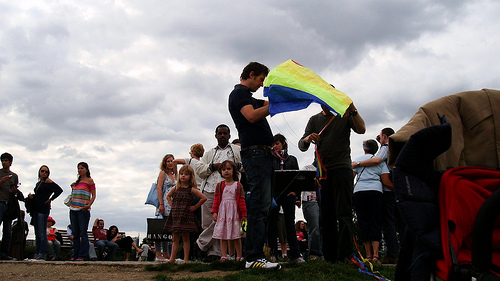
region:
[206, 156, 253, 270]
young girl in pink dress with red sweater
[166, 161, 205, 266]
young blond girl in brown dress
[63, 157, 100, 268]
woman wearing jeans and multi-colored striped shirt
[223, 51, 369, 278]
two men with yellow and blue kite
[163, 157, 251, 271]
two young girls in dresses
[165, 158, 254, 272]
one blond girl and one brunette girl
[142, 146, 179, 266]
woman in white and blue dress carrying blue bag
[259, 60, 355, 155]
yellow and blue parafoil kite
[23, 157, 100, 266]
two women wearing jeans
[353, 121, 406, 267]
man and woman wearing light blue shirts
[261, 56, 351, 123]
folded blue light green and yellow flag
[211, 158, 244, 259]
little blode girl wearing pink dress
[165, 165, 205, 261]
little blonde girl in black and red dress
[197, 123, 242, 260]
man wearing black clothes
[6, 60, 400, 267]
a bunch of people in a field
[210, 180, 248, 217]
black sweater of little blonde girl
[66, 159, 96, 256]
woman wearing multicolored t-shirt and black pants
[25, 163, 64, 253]
woman wearing black t-shirt and black pants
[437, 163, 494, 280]
red scarf lying on a bench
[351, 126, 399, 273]
woman wearing light blue t-shirt and black pants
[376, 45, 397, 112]
There is a very large cloud in the sky here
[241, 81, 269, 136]
This man is wearing a black shirt here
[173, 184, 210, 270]
This little girl is wearing a dress here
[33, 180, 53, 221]
This woman is wearing a black shirt here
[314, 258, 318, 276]
There is a green patch of grass here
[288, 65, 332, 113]
There is a rather brightly color kite here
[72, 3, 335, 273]
Jans Zander took this photo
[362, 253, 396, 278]
This woman is wearing shoes here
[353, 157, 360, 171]
This man has a watch on his left wrist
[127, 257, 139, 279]
There is a patch of cement that is here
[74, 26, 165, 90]
this is the sky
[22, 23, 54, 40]
the sky is blue in color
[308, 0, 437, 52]
the sky has clouds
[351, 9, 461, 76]
the clouds are white in color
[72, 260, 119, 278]
this is the ground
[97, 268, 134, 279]
the ground has sand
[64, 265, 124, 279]
the sand is brown in color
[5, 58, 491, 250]
these are the people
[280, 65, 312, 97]
these are some clothes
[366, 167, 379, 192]
the t-shirt is white in color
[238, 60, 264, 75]
Man has dark hair.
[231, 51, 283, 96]
Man has short hair.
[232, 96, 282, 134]
Man wearing black shirt.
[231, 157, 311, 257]
Man wearing blue jeans.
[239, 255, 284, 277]
Man wearing white and yellow shoes.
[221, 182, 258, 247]
Girl wearing pink dress.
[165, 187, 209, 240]
Girl wearing little brown dress.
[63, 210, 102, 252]
Woman wearing blue jeans.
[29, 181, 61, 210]
Person wearing black shirt.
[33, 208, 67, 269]
Person wearing jeans.